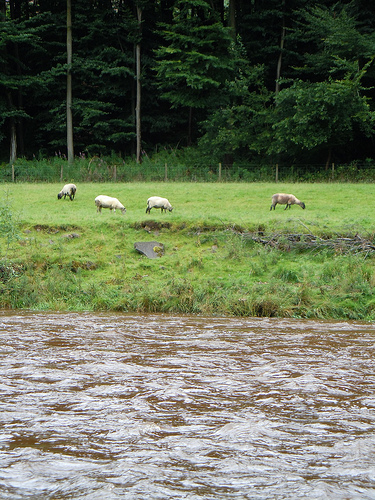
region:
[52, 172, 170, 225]
a group of sheep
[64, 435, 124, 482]
the ripples in a river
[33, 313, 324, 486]
a big brown river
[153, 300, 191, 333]
the coast of a river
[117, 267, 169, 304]
a big field of grass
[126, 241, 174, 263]
a large rock in the ground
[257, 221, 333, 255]
a bunch of brown twigs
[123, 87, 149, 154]
a long brown tree trunk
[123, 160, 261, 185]
a small wire fence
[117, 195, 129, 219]
the head of a sheep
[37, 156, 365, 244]
a group of sheeps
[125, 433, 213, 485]
riddles in the water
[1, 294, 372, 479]
a view of water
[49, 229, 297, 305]
green grass in the field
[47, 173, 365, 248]
a group of sheeps in field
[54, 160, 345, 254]
a group of sheeps in grass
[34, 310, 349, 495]
water flowing near grass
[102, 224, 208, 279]
a stone in grass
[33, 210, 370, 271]
a view of stones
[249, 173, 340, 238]
a sheep eating in grass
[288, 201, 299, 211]
leg of a sheep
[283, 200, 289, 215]
leg of a sheep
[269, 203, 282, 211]
leg of a sheep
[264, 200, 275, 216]
leg of a sheep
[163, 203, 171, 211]
leg of a sheep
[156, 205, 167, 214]
leg of a sheep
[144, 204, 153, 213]
leg of a sheep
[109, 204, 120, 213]
leg of a sheep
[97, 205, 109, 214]
leg of a sheep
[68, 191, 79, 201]
leg of a sheep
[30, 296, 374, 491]
a clear view of wate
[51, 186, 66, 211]
head of the sheep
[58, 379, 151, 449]
riddles in the water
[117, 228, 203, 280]
a rock in grass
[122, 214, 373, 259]
a group of stones in grass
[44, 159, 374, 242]
four sheeps eating food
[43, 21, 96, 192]
a long tree in the back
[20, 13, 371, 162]
a group of green trees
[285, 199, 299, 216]
leg of a sheep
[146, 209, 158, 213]
leg of a sheep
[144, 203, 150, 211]
leg of a sheep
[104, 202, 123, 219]
leg of a sheep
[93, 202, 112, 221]
leg of a sheep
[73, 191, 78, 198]
leg of a sheep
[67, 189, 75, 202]
leg of a sheep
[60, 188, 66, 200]
leg of a sheep